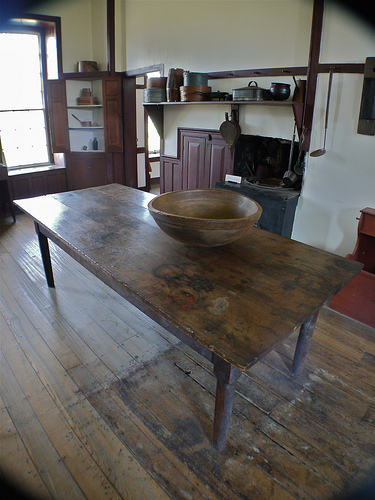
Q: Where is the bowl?
A: On the table.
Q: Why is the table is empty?
A: No one is using it.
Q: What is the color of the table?
A: Brown.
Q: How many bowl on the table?
A: One.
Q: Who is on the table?
A: No one.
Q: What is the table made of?
A: Wood.